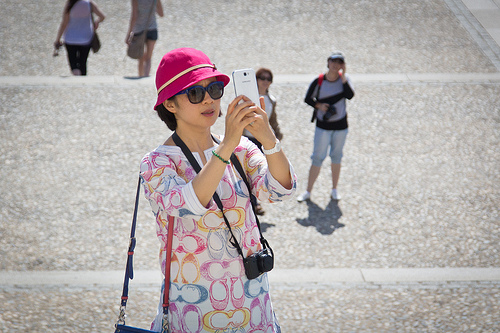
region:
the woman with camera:
[83, 32, 322, 330]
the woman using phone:
[114, 45, 311, 327]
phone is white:
[221, 65, 273, 124]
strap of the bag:
[113, 177, 148, 322]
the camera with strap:
[240, 244, 287, 277]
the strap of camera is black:
[165, 135, 215, 171]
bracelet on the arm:
[211, 148, 235, 168]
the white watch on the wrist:
[257, 136, 285, 158]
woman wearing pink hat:
[132, 35, 242, 115]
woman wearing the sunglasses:
[175, 81, 226, 109]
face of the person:
[134, 54, 304, 177]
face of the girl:
[136, 15, 254, 131]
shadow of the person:
[293, 185, 386, 264]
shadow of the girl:
[303, 52, 356, 269]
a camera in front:
[199, 135, 294, 282]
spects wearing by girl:
[185, 70, 248, 110]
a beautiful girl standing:
[146, 42, 335, 326]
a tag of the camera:
[173, 153, 248, 268]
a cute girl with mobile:
[136, 35, 308, 317]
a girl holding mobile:
[236, 49, 272, 157]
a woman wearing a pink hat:
[145, 45, 234, 125]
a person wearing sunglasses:
[177, 80, 224, 106]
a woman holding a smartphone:
[151, 50, 279, 148]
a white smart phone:
[229, 66, 261, 114]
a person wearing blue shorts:
[308, 127, 352, 171]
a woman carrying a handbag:
[76, 2, 115, 60]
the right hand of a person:
[222, 97, 249, 145]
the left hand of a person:
[246, 96, 267, 135]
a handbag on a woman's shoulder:
[103, 131, 187, 331]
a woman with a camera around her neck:
[171, 118, 278, 283]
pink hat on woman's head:
[154, 49, 232, 87]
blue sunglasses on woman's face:
[188, 81, 228, 104]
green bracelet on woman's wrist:
[207, 145, 232, 167]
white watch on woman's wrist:
[264, 131, 287, 162]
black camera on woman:
[237, 242, 281, 280]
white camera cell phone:
[232, 68, 259, 115]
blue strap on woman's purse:
[116, 190, 137, 330]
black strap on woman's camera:
[236, 160, 272, 250]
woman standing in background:
[296, 52, 356, 206]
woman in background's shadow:
[294, 201, 347, 242]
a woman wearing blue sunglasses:
[125, 33, 232, 168]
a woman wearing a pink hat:
[136, 40, 250, 172]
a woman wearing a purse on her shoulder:
[91, 40, 246, 330]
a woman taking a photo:
[138, 35, 265, 165]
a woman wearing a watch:
[146, 48, 322, 194]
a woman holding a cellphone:
[138, 35, 293, 165]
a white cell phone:
[207, 48, 277, 135]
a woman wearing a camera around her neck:
[149, 30, 304, 299]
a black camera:
[168, 129, 304, 288]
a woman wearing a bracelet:
[138, 47, 238, 193]